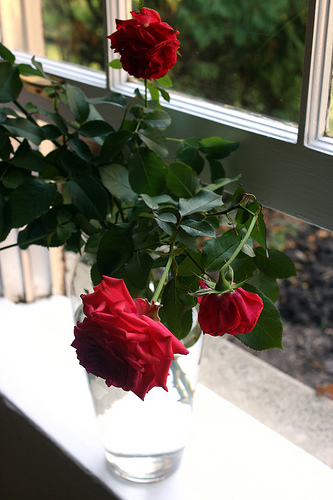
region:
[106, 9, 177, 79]
an open red rose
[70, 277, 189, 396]
an opened red rose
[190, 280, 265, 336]
an opened red rose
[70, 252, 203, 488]
a clear glass vase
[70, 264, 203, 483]
a glass filled with water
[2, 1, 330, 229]
an opened window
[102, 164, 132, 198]
a green rose leaf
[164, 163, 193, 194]
a green rose leaf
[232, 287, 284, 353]
a green rose leaf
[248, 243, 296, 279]
a green rose leaf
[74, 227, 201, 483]
the vase is on the window sill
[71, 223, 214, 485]
the vase is glass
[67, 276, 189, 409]
the rose is red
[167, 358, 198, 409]
the rose stem is in the vase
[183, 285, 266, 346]
the small rose is drooping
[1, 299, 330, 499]
the window sill is white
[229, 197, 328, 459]
the window is open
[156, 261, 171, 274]
the thorns are on the stems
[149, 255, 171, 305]
the stems are green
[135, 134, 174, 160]
the leaves are green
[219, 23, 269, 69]
window next to rose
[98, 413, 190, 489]
water in the vase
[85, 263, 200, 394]
red rose in vase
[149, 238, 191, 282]
green stem below the rose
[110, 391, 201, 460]
clear glass with rose in it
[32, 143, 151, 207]
leaves next to the rose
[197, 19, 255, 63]
blurry background of photo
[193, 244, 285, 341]
rose pointing down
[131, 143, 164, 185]
leaf next to the rose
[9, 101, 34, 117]
stem of the leaf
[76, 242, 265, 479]
roses in glass vase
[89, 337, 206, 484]
water in glass vase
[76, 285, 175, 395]
rose with curled leaves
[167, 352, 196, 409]
rose stems in water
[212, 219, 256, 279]
green stem of rose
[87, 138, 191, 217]
green leaves of roses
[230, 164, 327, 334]
open window behind vase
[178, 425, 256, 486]
white sill of window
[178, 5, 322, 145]
glass of window pane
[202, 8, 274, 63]
blurred leaves of bushes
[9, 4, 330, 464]
an open window here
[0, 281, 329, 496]
a white windowpane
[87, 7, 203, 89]
a red rose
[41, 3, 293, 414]
some flowers in a vase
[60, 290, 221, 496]
a clear vase with water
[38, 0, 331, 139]
a green tree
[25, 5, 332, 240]
a white window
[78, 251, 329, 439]
grey sidewalk outside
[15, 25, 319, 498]
a scene inside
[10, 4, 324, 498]
a scene happening during the day